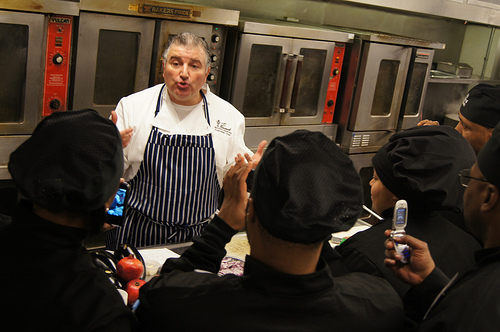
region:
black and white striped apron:
[128, 88, 214, 248]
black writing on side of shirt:
[203, 115, 236, 147]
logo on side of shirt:
[212, 120, 231, 137]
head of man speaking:
[151, 28, 218, 113]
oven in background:
[238, 43, 345, 123]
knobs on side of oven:
[318, 49, 349, 121]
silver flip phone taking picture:
[375, 201, 414, 264]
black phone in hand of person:
[113, 184, 133, 214]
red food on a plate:
[109, 250, 154, 320]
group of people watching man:
[20, 95, 493, 330]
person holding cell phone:
[0, 105, 131, 329]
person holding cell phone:
[133, 122, 398, 329]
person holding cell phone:
[340, 125, 487, 315]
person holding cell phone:
[405, 74, 497, 178]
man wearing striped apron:
[100, 31, 264, 249]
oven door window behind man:
[2, 18, 32, 126]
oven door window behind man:
[90, 24, 138, 106]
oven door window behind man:
[238, 42, 282, 119]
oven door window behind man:
[288, 42, 326, 114]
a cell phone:
[393, 201, 416, 262]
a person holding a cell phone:
[393, 128, 497, 296]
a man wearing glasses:
[451, 136, 496, 212]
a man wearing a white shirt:
[116, 42, 251, 234]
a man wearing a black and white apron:
[124, 46, 239, 223]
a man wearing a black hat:
[203, 130, 378, 324]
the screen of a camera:
[91, 179, 131, 235]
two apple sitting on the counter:
[111, 243, 151, 305]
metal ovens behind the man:
[7, 8, 414, 153]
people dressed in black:
[13, 101, 490, 311]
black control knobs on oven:
[327, 50, 344, 84]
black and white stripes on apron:
[149, 134, 210, 222]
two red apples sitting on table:
[118, 252, 153, 301]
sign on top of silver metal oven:
[133, 0, 206, 21]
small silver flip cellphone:
[388, 194, 415, 268]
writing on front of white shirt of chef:
[209, 116, 239, 139]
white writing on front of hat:
[455, 85, 475, 117]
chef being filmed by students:
[2, 44, 498, 328]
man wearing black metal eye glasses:
[447, 162, 498, 223]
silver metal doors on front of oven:
[239, 37, 330, 136]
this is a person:
[202, 101, 332, 317]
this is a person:
[6, 115, 126, 317]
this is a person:
[367, 113, 471, 257]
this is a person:
[450, 73, 498, 211]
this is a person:
[80, 36, 265, 244]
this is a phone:
[362, 193, 432, 287]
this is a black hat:
[247, 129, 354, 254]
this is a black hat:
[8, 101, 128, 218]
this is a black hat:
[338, 106, 458, 233]